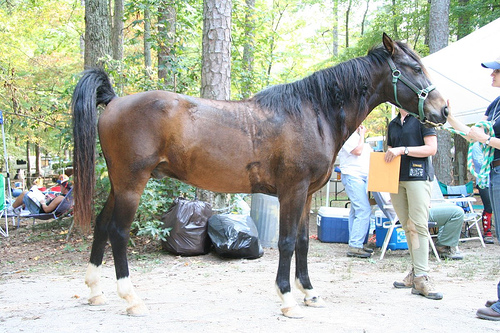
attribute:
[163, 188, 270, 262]
bags — trash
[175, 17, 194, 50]
leaves — green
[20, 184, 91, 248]
chair — round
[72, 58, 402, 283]
brown horse — large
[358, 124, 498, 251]
chair — lawn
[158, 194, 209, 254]
bag — garbage, larger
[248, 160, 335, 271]
can — silver, metal, garbage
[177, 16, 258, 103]
trunk — tall, tree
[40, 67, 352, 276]
horse — brown , black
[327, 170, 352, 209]
table — small, section, folding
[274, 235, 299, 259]
knee — part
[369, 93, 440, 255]
man — light skinned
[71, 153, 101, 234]
tail — part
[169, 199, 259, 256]
bag — paper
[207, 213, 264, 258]
bag — black, garbage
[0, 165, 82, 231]
person — reading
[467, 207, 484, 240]
sock — red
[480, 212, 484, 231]
dots — white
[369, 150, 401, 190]
envelope — brown